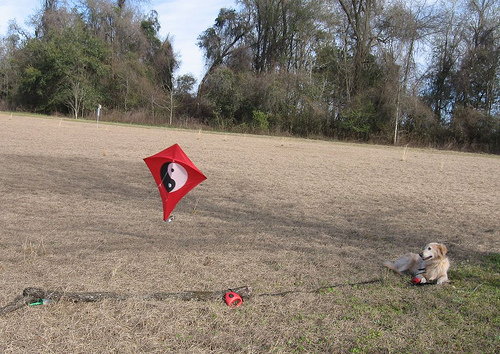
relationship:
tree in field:
[341, 3, 430, 129] [3, 15, 490, 344]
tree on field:
[35, 3, 112, 121] [4, 111, 485, 345]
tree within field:
[35, 3, 108, 121] [4, 111, 485, 345]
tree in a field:
[330, 0, 403, 142] [4, 111, 485, 345]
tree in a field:
[35, 3, 108, 121] [74, 85, 455, 299]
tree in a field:
[202, 31, 254, 99] [38, 108, 424, 321]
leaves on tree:
[300, 82, 318, 98] [199, 63, 331, 136]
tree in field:
[35, 3, 108, 121] [225, 155, 449, 218]